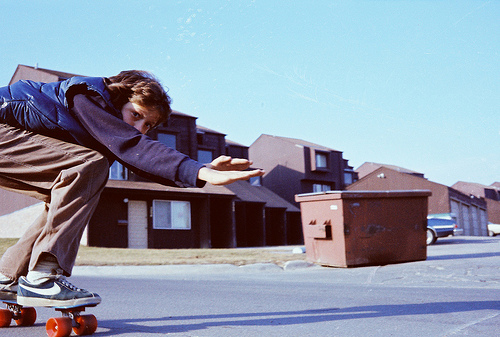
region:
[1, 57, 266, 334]
kid on a skate board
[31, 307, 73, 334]
red plastic skate board wheel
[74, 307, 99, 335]
red plastic skate board wheel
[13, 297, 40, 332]
red plastic skate board wheel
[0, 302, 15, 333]
red plastic skate board wheel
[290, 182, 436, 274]
large brown metal dumpster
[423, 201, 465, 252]
end of a parked blue car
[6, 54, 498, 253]
row of brown sub urban apartments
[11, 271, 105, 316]
dark blue and white nike shoes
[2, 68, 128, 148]
puffy blue vest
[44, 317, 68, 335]
wheel on the skateboard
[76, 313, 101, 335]
wheel on the skateboard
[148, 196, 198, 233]
window on the building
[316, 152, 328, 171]
window on the building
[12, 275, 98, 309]
shoe on the boy's foot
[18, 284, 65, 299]
logo on the shoe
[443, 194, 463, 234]
door on the garage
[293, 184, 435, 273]
trash can behind the house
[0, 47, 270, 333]
boy on the skate board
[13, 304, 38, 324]
wheel on the skateboard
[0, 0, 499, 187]
a large area of blue sky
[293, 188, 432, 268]
a large brown dumpster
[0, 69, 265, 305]
a boy riding a skateboard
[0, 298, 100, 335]
the boy's skateboard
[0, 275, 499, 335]
an asphalt road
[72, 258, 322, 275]
a concrete curb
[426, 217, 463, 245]
a blue car in the background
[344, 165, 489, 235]
a row of garages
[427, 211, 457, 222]
a pickup truck behind a car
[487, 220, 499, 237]
a car in the background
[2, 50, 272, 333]
a nascent skateboard dude prepares for a trick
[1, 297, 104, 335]
skateboard dude's wheels are red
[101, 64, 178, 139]
nascent skateboard dude's hair is rather long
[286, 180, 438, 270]
looks like a dumpster in the background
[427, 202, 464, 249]
a car is parked behind the dumpster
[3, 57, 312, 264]
this looks like a new housing development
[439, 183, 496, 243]
two double garages side by side in the background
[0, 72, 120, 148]
young skateboard dude is wearing a ski vest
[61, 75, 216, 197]
young skateboard dude is wearing a long sleeved sweatshirt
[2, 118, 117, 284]
young skateboard dude is wearing brown pants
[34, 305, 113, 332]
the wheels are red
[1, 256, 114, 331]
the boy is riding a skateboard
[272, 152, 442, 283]
the garbage bin is on the street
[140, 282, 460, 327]
shadow of the boy on the ground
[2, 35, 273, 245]
the boys arms are stretched out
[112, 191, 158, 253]
the door is closed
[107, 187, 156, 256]
the door is white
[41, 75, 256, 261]
the house is brown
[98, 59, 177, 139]
the boys hair is brown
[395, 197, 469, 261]
cars are parked side by side